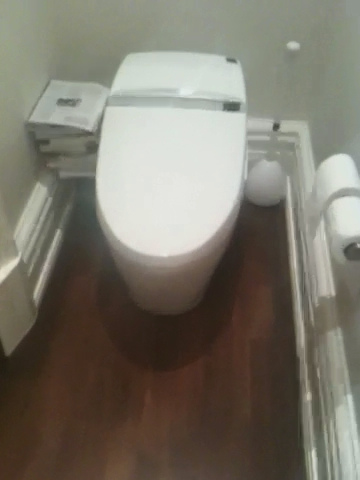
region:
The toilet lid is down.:
[93, 96, 241, 247]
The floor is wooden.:
[62, 384, 248, 454]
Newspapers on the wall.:
[38, 68, 93, 176]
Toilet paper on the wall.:
[312, 152, 355, 192]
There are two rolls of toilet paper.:
[308, 153, 358, 249]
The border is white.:
[290, 307, 342, 408]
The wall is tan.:
[39, 7, 135, 44]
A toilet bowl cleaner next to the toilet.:
[250, 108, 300, 214]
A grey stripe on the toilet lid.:
[101, 84, 250, 129]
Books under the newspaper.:
[52, 136, 93, 184]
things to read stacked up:
[14, 65, 95, 190]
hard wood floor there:
[96, 370, 138, 399]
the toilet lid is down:
[82, 45, 237, 330]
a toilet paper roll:
[302, 157, 344, 213]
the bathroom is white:
[209, 17, 273, 112]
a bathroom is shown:
[16, 19, 284, 158]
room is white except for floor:
[8, 102, 353, 317]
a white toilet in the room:
[73, 35, 310, 229]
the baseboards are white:
[289, 162, 326, 199]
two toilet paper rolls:
[301, 153, 357, 240]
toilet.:
[49, 130, 264, 278]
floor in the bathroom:
[91, 395, 259, 429]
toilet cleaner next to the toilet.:
[257, 110, 286, 170]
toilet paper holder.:
[314, 117, 351, 209]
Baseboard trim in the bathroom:
[9, 201, 68, 301]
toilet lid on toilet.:
[56, 106, 328, 346]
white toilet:
[104, 106, 306, 309]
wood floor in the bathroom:
[84, 303, 232, 360]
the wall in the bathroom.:
[247, 14, 317, 83]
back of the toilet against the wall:
[114, 36, 265, 77]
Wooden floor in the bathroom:
[51, 322, 161, 478]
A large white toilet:
[92, 66, 253, 325]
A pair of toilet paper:
[316, 149, 358, 266]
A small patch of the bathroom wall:
[79, 7, 154, 50]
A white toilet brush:
[246, 109, 292, 214]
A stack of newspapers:
[30, 69, 103, 183]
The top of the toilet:
[108, 45, 252, 99]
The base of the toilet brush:
[244, 161, 289, 212]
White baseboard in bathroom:
[296, 302, 351, 478]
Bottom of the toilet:
[127, 298, 219, 320]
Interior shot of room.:
[6, 5, 357, 466]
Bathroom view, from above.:
[6, 8, 359, 473]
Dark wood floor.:
[79, 351, 221, 451]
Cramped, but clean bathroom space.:
[8, 16, 351, 475]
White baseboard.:
[295, 319, 359, 463]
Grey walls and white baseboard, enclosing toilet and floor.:
[5, 19, 357, 466]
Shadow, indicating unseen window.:
[87, 252, 235, 381]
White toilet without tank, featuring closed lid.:
[113, 50, 237, 336]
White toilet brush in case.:
[252, 112, 284, 212]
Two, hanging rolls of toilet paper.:
[320, 145, 359, 273]